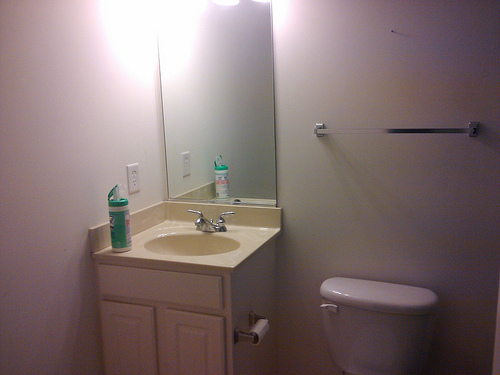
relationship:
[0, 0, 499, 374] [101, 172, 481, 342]
bathroom of bathroom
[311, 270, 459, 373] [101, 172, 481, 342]
toilet in bathroom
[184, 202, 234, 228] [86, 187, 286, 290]
handles on sink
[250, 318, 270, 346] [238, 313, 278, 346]
roll on roll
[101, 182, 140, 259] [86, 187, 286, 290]
wipes on a counter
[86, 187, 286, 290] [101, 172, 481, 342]
sink on a bathroom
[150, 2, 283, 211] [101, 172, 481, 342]
mirror in bathroom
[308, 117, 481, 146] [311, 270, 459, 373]
towel rack above toilet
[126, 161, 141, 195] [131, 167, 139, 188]
electric for electric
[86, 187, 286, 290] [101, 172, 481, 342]
sink in bathroom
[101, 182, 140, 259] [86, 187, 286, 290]
wipes on sink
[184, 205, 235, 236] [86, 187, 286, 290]
water valve on sink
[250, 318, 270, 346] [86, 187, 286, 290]
roll on sink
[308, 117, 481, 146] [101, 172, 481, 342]
towel rack in bathroom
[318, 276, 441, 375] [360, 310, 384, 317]
toilet for water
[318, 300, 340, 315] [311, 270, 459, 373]
handle to flush toilet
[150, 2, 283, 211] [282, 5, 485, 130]
mirror on wall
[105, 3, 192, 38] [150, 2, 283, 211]
light on mirror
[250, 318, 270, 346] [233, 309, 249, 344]
roll of holder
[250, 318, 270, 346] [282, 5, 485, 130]
roll roll on wall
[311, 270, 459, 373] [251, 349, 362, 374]
toilet with seat down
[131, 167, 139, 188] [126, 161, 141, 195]
electric twin style electric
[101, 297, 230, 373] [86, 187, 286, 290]
door under sink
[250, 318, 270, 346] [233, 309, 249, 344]
roll in holder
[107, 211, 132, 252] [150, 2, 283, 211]
container in mirror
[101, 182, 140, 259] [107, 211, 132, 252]
wipes inside container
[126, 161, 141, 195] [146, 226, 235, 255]
electric above counter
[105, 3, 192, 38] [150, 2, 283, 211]
light shining on mirror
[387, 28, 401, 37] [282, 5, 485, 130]
nail hanging in wall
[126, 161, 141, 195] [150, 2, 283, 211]
electric in mirror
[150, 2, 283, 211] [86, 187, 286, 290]
mirror above sink